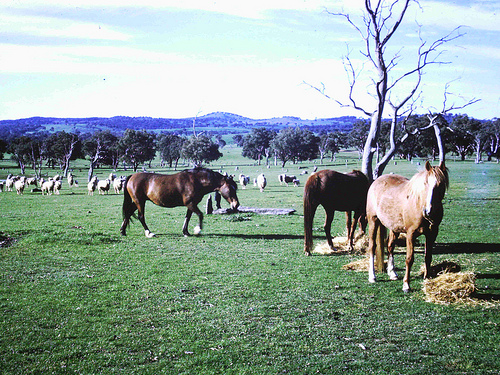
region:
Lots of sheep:
[4, 169, 121, 194]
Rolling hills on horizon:
[7, 111, 302, 125]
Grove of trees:
[2, 128, 495, 168]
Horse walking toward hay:
[111, 166, 237, 241]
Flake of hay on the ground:
[415, 265, 482, 307]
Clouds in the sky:
[2, 7, 482, 82]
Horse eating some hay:
[295, 166, 370, 251]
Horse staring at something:
[361, 156, 447, 294]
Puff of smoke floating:
[460, 160, 495, 205]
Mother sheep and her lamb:
[278, 172, 301, 187]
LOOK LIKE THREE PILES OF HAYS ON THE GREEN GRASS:
[307, 229, 495, 311]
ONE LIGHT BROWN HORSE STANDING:
[365, 156, 450, 296]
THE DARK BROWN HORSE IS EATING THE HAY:
[293, 168, 374, 255]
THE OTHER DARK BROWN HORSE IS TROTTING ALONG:
[120, 168, 243, 240]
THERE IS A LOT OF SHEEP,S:
[0, 163, 306, 198]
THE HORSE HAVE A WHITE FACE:
[423, 175, 438, 222]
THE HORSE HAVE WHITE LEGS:
[362, 249, 432, 297]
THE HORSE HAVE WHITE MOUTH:
[228, 198, 240, 210]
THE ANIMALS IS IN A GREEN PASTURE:
[0, 136, 498, 373]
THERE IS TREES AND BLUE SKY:
[0, 0, 496, 161]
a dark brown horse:
[109, 166, 244, 241]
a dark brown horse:
[293, 162, 376, 260]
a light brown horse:
[357, 156, 455, 296]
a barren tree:
[295, 0, 481, 171]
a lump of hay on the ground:
[417, 256, 497, 316]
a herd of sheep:
[0, 172, 127, 196]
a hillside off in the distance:
[2, 106, 368, 129]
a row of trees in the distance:
[0, 127, 365, 167]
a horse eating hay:
[292, 164, 376, 256]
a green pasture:
[4, 235, 303, 367]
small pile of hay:
[419, 266, 491, 323]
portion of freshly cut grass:
[15, 238, 317, 357]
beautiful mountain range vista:
[8, 104, 336, 136]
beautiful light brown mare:
[363, 164, 452, 279]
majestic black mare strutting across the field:
[116, 164, 243, 236]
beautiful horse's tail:
[118, 170, 141, 229]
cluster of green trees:
[8, 125, 175, 170]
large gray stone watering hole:
[218, 202, 296, 224]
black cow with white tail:
[276, 172, 299, 187]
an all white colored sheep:
[98, 177, 111, 199]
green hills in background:
[1, 106, 496, 149]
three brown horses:
[115, 161, 447, 291]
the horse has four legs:
[365, 210, 440, 291]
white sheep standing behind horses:
[0, 167, 312, 192]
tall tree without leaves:
[290, 0, 485, 215]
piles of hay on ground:
[305, 220, 497, 315]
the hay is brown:
[305, 220, 495, 315]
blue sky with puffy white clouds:
[0, 2, 497, 118]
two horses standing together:
[301, 160, 451, 296]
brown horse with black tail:
[117, 166, 242, 242]